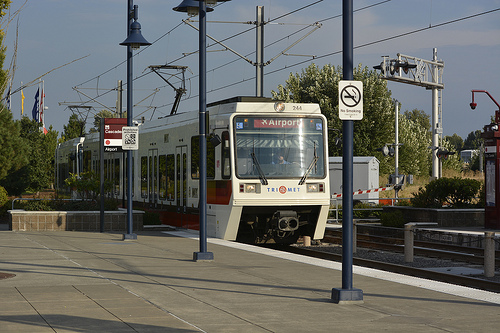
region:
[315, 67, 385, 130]
a no smoking sign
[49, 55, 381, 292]
a train pulls in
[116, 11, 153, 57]
an overhead light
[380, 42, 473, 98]
a large sign over traffic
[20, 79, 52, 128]
several flags hang from poles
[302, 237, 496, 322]
train tracks with rocks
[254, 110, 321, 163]
a sign saying airport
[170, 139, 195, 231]
doors to the train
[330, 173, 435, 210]
a automatic gate stopping traffic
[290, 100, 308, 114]
the number of the train 244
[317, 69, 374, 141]
black and white sign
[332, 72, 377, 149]
a no smoking sign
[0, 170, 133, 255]
green plants in a planting area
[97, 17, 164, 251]
blue light pole and pole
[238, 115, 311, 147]
red and white sign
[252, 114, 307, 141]
sign that says airport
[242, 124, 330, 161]
shield for sun in window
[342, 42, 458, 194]
tall silver pole with rail road signal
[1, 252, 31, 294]
part of a metal grate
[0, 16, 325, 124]
telephone poles and wires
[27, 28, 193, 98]
Sky is blue color.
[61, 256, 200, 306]
Pavement is brown color.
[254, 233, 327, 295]
White lines in pavement.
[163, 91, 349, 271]
Train is white color.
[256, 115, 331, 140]
Airport is written in train.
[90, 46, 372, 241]
Poles are blue color.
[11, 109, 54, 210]
Leaves are green color.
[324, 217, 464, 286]
Track is brown color.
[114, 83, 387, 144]
Boards are attached to the pole.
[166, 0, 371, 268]
Power cords are running above the train.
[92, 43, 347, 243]
a train traveling down tracks.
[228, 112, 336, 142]
a marque on a train.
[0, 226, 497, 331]
a loading platform at a train station.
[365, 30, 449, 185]
a train traffic signal.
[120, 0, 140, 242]
a pole near a train.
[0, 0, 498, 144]
a hazy blue sky.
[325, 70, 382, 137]
a sign on a pole.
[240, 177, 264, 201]
a train headlight.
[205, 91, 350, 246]
the front of a white train.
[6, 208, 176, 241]
a sitting area near a train.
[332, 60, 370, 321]
the sign is on a pole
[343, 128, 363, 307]
the pole is dark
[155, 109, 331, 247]
the train is white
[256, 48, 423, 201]
the trees are behind train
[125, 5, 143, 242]
the light is hanging from pole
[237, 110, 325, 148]
the sign is red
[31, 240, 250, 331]
the platform is gray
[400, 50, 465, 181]
the light post is silver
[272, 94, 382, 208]
electric box behind train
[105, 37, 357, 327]
the poles are on the platform